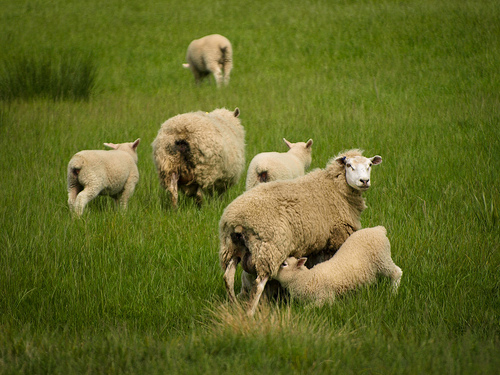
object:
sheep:
[180, 32, 234, 88]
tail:
[215, 42, 230, 54]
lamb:
[270, 224, 402, 311]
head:
[331, 146, 382, 192]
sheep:
[147, 105, 246, 209]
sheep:
[216, 146, 382, 320]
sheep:
[64, 138, 140, 219]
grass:
[0, 0, 499, 374]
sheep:
[241, 135, 314, 194]